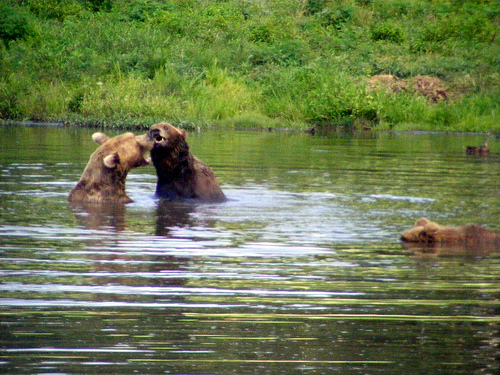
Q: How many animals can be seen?
A: 3.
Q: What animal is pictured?
A: Bears.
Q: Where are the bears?
A: In Water.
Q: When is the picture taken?
A: Daytime.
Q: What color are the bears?
A: Brown.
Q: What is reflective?
A: Water.